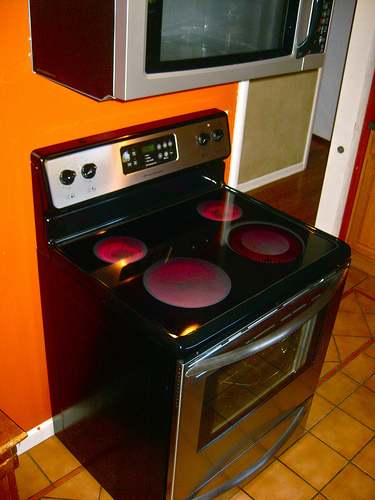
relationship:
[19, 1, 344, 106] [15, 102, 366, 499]
microwave above oven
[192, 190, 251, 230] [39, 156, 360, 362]
burner on surface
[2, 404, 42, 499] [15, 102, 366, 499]
table near stove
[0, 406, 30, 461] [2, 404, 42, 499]
corner of table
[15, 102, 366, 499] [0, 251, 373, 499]
range on floor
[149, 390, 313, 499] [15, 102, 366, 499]
drawer on range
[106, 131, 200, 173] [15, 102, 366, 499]
console on oven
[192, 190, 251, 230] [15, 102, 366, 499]
burner on range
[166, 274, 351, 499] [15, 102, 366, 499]
door on oven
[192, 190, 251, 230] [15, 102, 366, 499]
burner on stove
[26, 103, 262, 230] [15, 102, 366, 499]
panel for oven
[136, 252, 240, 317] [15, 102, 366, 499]
burner on stove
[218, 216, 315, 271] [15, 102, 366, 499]
burner on stove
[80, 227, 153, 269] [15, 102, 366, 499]
burner on stove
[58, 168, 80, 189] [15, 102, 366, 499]
knob on stove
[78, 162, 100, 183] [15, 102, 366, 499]
knob on stove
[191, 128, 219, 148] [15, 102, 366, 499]
knob on stove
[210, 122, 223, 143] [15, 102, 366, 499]
knob on stove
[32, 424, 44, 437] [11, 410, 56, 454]
paint on baseboard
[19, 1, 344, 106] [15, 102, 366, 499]
microwave above stove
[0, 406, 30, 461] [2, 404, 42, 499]
corner of countertop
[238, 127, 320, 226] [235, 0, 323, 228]
floor in hallway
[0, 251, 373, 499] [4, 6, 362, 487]
tile in kitchen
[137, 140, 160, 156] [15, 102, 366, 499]
clock on stove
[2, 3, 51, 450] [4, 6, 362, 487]
wall in kitchen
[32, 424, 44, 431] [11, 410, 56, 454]
spot on baseboard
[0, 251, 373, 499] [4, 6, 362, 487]
floor in kitchen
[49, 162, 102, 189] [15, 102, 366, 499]
dials on oven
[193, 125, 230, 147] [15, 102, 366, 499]
dials on oven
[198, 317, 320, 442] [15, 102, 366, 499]
window on oven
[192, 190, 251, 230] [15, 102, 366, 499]
burner of stove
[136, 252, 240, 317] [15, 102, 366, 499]
burner of stove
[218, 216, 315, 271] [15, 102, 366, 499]
burner of stove